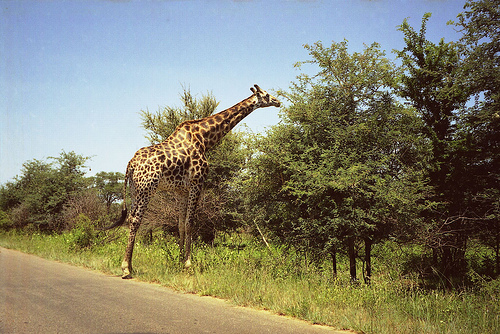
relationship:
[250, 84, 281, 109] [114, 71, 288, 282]
head of a giraffe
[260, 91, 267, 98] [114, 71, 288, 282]
ear of a giraffe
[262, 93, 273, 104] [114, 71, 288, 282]
eye of a giraffe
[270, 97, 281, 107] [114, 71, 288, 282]
mouth of a giraffe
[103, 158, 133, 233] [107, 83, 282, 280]
tail of a giraffe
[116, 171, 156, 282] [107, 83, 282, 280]
back legs of a giraffe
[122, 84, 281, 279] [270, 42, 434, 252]
giraffe eating leaves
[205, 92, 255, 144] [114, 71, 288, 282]
neck belonging to giraffe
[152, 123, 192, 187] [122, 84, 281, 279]
body belonging to giraffe